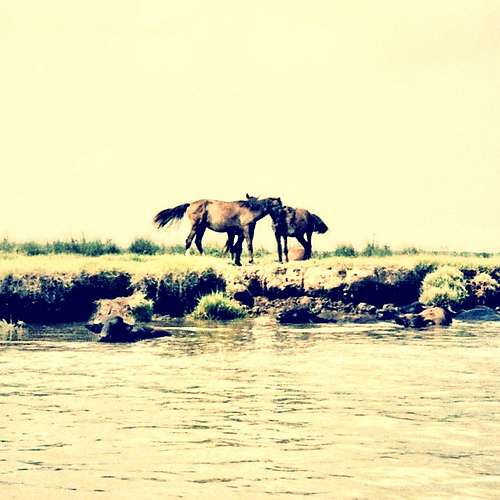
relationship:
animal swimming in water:
[83, 315, 171, 342] [0, 326, 500, 498]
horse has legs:
[153, 198, 283, 267] [135, 168, 336, 292]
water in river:
[6, 301, 483, 488] [8, 315, 483, 489]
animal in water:
[83, 315, 171, 342] [179, 391, 286, 442]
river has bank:
[8, 315, 483, 489] [7, 257, 484, 331]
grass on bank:
[420, 265, 462, 309] [7, 257, 484, 331]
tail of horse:
[154, 204, 189, 229] [180, 188, 288, 265]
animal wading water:
[83, 315, 171, 342] [312, 412, 441, 459]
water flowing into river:
[135, 332, 430, 413] [8, 315, 483, 489]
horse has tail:
[153, 198, 283, 267] [149, 201, 181, 227]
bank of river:
[0, 243, 500, 333] [8, 315, 483, 489]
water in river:
[240, 339, 369, 435] [7, 295, 484, 490]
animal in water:
[83, 315, 171, 342] [6, 301, 483, 488]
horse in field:
[260, 190, 336, 260] [2, 235, 499, 291]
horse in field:
[153, 198, 283, 267] [2, 235, 499, 291]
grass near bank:
[2, 240, 498, 270] [1, 260, 496, 328]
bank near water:
[1, 260, 496, 328] [0, 326, 500, 498]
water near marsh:
[0, 326, 500, 498] [2, 269, 499, 347]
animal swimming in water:
[80, 317, 172, 346] [2, 309, 498, 497]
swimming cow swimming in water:
[274, 295, 331, 330] [2, 309, 498, 497]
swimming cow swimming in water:
[395, 300, 460, 328] [2, 309, 498, 497]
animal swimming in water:
[83, 315, 171, 342] [2, 309, 498, 497]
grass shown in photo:
[59, 239, 133, 269] [1, 2, 483, 498]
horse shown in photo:
[153, 180, 283, 267] [1, 2, 483, 498]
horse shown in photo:
[273, 204, 331, 260] [1, 2, 483, 498]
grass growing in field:
[2, 240, 498, 270] [1, 238, 484, 302]